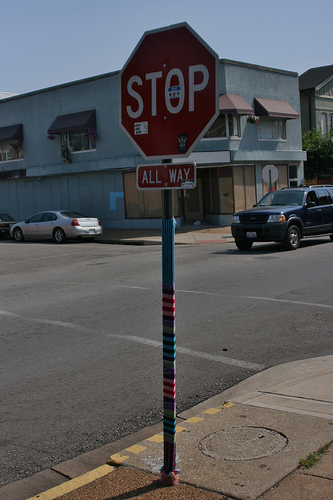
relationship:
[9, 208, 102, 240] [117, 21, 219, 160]
car behind stop sign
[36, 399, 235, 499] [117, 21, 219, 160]
curb below stop sign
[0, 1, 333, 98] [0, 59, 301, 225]
sky above building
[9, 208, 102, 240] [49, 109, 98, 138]
car below awning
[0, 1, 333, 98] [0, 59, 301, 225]
sky abovve building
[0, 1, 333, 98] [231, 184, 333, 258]
sky above suv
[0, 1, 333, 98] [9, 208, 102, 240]
sky above car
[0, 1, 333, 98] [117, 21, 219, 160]
sky above stop sign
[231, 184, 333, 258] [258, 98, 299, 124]
suv below awning